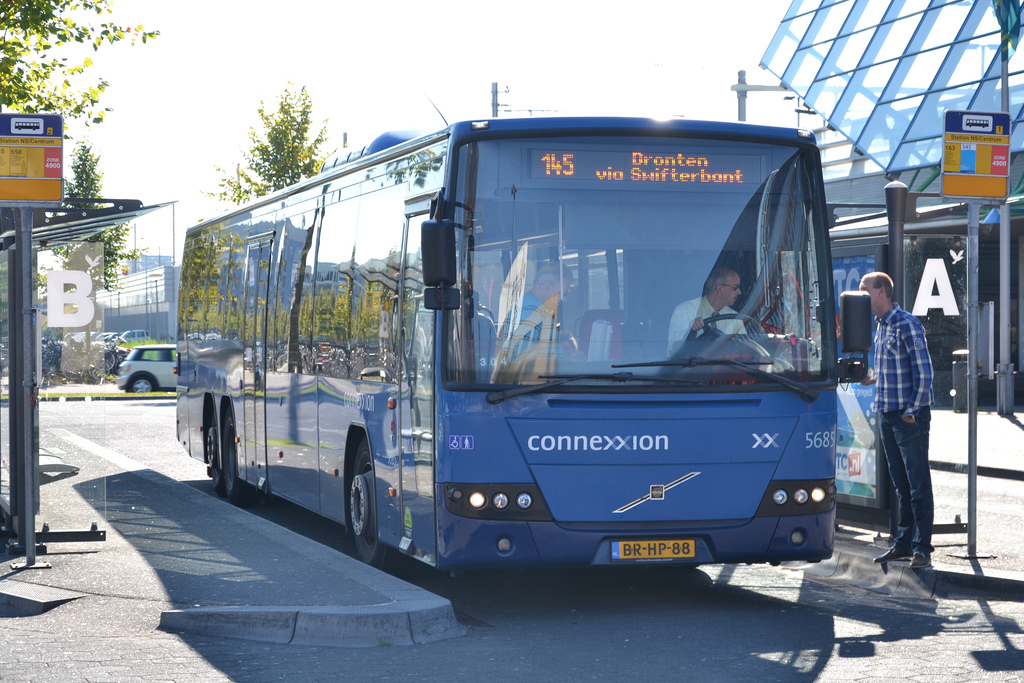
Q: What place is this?
A: It is a street.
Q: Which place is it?
A: It is a street.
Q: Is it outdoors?
A: Yes, it is outdoors.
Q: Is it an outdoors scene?
A: Yes, it is outdoors.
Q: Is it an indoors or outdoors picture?
A: It is outdoors.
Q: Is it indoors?
A: No, it is outdoors.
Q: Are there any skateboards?
A: No, there are no skateboards.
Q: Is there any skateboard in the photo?
A: No, there are no skateboards.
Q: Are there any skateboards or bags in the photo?
A: No, there are no skateboards or bags.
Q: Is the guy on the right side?
A: Yes, the guy is on the right of the image.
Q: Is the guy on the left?
A: No, the guy is on the right of the image.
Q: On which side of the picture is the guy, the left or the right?
A: The guy is on the right of the image.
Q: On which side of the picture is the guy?
A: The guy is on the right of the image.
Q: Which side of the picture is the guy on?
A: The guy is on the right of the image.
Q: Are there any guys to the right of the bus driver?
A: Yes, there is a guy to the right of the bus driver.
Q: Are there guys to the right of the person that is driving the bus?
A: Yes, there is a guy to the right of the bus driver.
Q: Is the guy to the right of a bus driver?
A: Yes, the guy is to the right of a bus driver.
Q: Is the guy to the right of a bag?
A: No, the guy is to the right of a bus driver.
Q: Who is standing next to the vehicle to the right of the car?
A: The guy is standing next to the bus.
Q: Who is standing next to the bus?
A: The guy is standing next to the bus.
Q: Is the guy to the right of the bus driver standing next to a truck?
A: No, the guy is standing next to the bus.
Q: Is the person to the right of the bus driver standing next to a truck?
A: No, the guy is standing next to the bus.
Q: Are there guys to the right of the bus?
A: Yes, there is a guy to the right of the bus.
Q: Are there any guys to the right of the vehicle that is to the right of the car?
A: Yes, there is a guy to the right of the bus.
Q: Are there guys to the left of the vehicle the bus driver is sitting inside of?
A: No, the guy is to the right of the bus.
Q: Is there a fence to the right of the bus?
A: No, there is a guy to the right of the bus.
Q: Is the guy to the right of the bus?
A: Yes, the guy is to the right of the bus.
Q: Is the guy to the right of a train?
A: No, the guy is to the right of the bus.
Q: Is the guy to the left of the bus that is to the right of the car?
A: No, the guy is to the right of the bus.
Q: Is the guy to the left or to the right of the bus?
A: The guy is to the right of the bus.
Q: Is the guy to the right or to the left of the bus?
A: The guy is to the right of the bus.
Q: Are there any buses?
A: Yes, there is a bus.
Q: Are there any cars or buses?
A: Yes, there is a bus.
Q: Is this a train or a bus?
A: This is a bus.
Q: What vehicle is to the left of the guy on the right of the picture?
A: The vehicle is a bus.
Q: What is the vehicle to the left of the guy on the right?
A: The vehicle is a bus.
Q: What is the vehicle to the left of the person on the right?
A: The vehicle is a bus.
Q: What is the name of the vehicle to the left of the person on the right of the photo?
A: The vehicle is a bus.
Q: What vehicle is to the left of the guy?
A: The vehicle is a bus.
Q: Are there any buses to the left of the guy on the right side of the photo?
A: Yes, there is a bus to the left of the guy.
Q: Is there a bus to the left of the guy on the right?
A: Yes, there is a bus to the left of the guy.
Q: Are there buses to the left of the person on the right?
A: Yes, there is a bus to the left of the guy.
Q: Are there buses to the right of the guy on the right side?
A: No, the bus is to the left of the guy.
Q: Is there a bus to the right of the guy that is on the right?
A: No, the bus is to the left of the guy.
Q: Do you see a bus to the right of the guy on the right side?
A: No, the bus is to the left of the guy.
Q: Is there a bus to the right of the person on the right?
A: No, the bus is to the left of the guy.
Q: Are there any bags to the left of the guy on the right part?
A: No, there is a bus to the left of the guy.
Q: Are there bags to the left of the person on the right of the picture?
A: No, there is a bus to the left of the guy.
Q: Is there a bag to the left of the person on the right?
A: No, there is a bus to the left of the guy.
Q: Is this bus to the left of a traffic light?
A: No, the bus is to the left of the guy.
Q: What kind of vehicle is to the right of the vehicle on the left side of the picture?
A: The vehicle is a bus.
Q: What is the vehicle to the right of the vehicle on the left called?
A: The vehicle is a bus.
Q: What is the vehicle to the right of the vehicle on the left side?
A: The vehicle is a bus.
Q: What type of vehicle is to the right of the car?
A: The vehicle is a bus.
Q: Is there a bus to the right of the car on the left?
A: Yes, there is a bus to the right of the car.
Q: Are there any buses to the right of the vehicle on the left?
A: Yes, there is a bus to the right of the car.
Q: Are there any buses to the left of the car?
A: No, the bus is to the right of the car.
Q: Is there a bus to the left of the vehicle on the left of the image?
A: No, the bus is to the right of the car.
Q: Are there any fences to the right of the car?
A: No, there is a bus to the right of the car.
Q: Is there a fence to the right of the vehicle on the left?
A: No, there is a bus to the right of the car.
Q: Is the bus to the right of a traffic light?
A: No, the bus is to the right of the car.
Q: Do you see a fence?
A: No, there are no fences.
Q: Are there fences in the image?
A: No, there are no fences.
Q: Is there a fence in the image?
A: No, there are no fences.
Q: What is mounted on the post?
A: The sign is mounted on the post.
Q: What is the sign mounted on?
A: The sign is mounted on the post.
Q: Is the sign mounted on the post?
A: Yes, the sign is mounted on the post.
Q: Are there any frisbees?
A: No, there are no frisbees.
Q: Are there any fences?
A: No, there are no fences.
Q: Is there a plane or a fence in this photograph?
A: No, there are no fences or airplanes.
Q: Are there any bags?
A: No, there are no bags.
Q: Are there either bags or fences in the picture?
A: No, there are no bags or fences.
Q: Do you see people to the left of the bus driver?
A: Yes, there is a person to the left of the bus driver.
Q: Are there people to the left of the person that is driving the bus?
A: Yes, there is a person to the left of the bus driver.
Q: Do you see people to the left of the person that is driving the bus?
A: Yes, there is a person to the left of the bus driver.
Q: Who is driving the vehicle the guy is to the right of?
A: The bus driver is driving the bus.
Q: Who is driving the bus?
A: The bus driver is driving the bus.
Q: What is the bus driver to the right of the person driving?
A: The bus driver is driving the bus.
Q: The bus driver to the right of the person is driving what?
A: The bus driver is driving the bus.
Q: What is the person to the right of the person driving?
A: The bus driver is driving the bus.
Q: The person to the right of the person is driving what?
A: The bus driver is driving the bus.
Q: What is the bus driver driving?
A: The bus driver is driving the bus.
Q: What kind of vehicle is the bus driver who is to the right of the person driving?
A: The bus driver is driving the bus.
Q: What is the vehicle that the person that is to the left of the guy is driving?
A: The vehicle is a bus.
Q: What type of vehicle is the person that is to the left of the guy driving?
A: The bus driver is driving the bus.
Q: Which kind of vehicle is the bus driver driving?
A: The bus driver is driving the bus.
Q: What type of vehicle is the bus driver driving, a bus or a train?
A: The bus driver is driving a bus.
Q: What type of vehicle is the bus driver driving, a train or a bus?
A: The bus driver is driving a bus.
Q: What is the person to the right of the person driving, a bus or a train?
A: The bus driver is driving a bus.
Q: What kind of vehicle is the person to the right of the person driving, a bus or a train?
A: The bus driver is driving a bus.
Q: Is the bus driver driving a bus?
A: Yes, the bus driver is driving a bus.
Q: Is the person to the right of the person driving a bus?
A: Yes, the bus driver is driving a bus.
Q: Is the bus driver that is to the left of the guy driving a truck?
A: No, the bus driver is driving a bus.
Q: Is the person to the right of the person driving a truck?
A: No, the bus driver is driving a bus.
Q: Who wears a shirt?
A: The bus driver wears a shirt.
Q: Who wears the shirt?
A: The bus driver wears a shirt.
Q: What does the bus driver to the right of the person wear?
A: The bus driver wears a shirt.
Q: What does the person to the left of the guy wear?
A: The bus driver wears a shirt.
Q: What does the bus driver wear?
A: The bus driver wears a shirt.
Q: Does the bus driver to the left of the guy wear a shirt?
A: Yes, the bus driver wears a shirt.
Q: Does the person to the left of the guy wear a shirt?
A: Yes, the bus driver wears a shirt.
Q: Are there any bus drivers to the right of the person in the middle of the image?
A: Yes, there is a bus driver to the right of the person.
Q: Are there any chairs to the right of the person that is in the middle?
A: No, there is a bus driver to the right of the person.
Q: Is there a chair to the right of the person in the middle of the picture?
A: No, there is a bus driver to the right of the person.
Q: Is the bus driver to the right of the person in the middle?
A: Yes, the bus driver is to the right of the person.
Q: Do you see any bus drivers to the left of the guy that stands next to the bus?
A: Yes, there is a bus driver to the left of the guy.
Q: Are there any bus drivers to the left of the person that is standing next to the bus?
A: Yes, there is a bus driver to the left of the guy.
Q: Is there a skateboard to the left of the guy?
A: No, there is a bus driver to the left of the guy.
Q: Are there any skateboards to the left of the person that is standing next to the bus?
A: No, there is a bus driver to the left of the guy.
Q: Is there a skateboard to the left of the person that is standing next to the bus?
A: No, there is a bus driver to the left of the guy.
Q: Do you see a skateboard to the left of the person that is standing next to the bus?
A: No, there is a bus driver to the left of the guy.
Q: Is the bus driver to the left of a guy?
A: Yes, the bus driver is to the left of a guy.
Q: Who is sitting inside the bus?
A: The bus driver is sitting inside the bus.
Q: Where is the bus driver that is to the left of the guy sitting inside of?
A: The bus driver is sitting inside the bus.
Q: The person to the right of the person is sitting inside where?
A: The bus driver is sitting inside the bus.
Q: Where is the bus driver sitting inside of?
A: The bus driver is sitting inside the bus.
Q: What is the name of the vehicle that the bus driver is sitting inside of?
A: The vehicle is a bus.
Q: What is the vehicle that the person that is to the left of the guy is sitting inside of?
A: The vehicle is a bus.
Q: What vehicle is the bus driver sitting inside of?
A: The bus driver is sitting inside the bus.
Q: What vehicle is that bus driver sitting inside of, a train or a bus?
A: The bus driver is sitting inside a bus.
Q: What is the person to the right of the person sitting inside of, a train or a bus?
A: The bus driver is sitting inside a bus.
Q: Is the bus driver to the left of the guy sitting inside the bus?
A: Yes, the bus driver is sitting inside the bus.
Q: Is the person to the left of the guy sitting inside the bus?
A: Yes, the bus driver is sitting inside the bus.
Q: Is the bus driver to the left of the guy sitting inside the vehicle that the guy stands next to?
A: Yes, the bus driver is sitting inside the bus.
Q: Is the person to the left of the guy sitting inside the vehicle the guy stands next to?
A: Yes, the bus driver is sitting inside the bus.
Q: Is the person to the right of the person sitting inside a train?
A: No, the bus driver is sitting inside the bus.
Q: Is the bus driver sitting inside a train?
A: No, the bus driver is sitting inside the bus.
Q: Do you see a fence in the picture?
A: No, there are no fences.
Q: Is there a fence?
A: No, there are no fences.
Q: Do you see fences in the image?
A: No, there are no fences.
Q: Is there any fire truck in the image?
A: No, there are no fire trucks.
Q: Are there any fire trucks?
A: No, there are no fire trucks.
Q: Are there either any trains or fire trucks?
A: No, there are no fire trucks or trains.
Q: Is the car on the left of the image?
A: Yes, the car is on the left of the image.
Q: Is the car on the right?
A: No, the car is on the left of the image.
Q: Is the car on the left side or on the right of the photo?
A: The car is on the left of the image.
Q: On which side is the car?
A: The car is on the left of the image.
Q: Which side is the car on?
A: The car is on the left of the image.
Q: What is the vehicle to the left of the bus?
A: The vehicle is a car.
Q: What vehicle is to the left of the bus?
A: The vehicle is a car.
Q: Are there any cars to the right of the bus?
A: No, the car is to the left of the bus.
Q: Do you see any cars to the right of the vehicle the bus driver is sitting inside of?
A: No, the car is to the left of the bus.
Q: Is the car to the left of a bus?
A: Yes, the car is to the left of a bus.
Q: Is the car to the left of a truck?
A: No, the car is to the left of a bus.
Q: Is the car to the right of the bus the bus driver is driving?
A: No, the car is to the left of the bus.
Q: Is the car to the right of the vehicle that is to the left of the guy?
A: No, the car is to the left of the bus.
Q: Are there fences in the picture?
A: No, there are no fences.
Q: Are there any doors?
A: Yes, there is a door.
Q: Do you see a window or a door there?
A: Yes, there is a door.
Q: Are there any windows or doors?
A: Yes, there is a door.